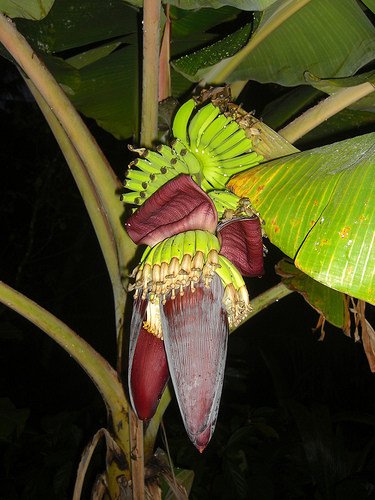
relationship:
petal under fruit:
[118, 168, 220, 247] [117, 93, 253, 413]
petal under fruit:
[210, 209, 265, 277] [117, 93, 253, 413]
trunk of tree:
[92, 354, 172, 499] [5, 2, 370, 495]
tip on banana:
[174, 146, 193, 158] [200, 230, 230, 268]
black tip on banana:
[133, 149, 148, 160] [139, 149, 166, 168]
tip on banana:
[114, 191, 126, 203] [117, 193, 125, 202]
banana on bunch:
[127, 103, 313, 217] [118, 222, 227, 303]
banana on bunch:
[202, 227, 221, 267] [118, 222, 227, 303]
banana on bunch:
[190, 224, 211, 271] [118, 222, 227, 303]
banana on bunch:
[179, 226, 198, 277] [118, 222, 227, 303]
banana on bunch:
[166, 229, 186, 276] [118, 222, 227, 303]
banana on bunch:
[157, 231, 174, 286] [118, 222, 227, 303]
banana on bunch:
[146, 235, 165, 285] [118, 222, 227, 303]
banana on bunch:
[139, 234, 160, 291] [118, 222, 227, 303]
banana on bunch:
[131, 239, 149, 296] [118, 222, 227, 303]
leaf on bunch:
[229, 129, 373, 338] [167, 89, 273, 190]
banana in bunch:
[169, 91, 190, 142] [167, 80, 269, 197]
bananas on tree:
[122, 93, 278, 329] [4, 19, 338, 477]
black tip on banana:
[170, 139, 176, 145] [153, 141, 174, 161]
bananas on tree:
[119, 95, 262, 230] [5, 2, 370, 495]